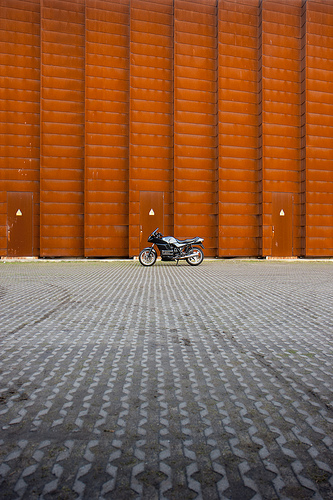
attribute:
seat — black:
[176, 237, 197, 243]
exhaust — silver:
[174, 252, 201, 260]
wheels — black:
[135, 247, 154, 266]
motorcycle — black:
[137, 225, 206, 269]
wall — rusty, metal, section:
[5, 25, 325, 248]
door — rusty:
[271, 193, 292, 257]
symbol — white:
[278, 209, 284, 215]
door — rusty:
[119, 180, 174, 247]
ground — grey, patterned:
[2, 261, 331, 498]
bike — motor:
[139, 225, 204, 265]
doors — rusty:
[3, 178, 301, 251]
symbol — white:
[269, 207, 293, 222]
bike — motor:
[119, 204, 212, 277]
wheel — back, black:
[186, 242, 212, 266]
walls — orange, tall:
[171, 60, 251, 140]